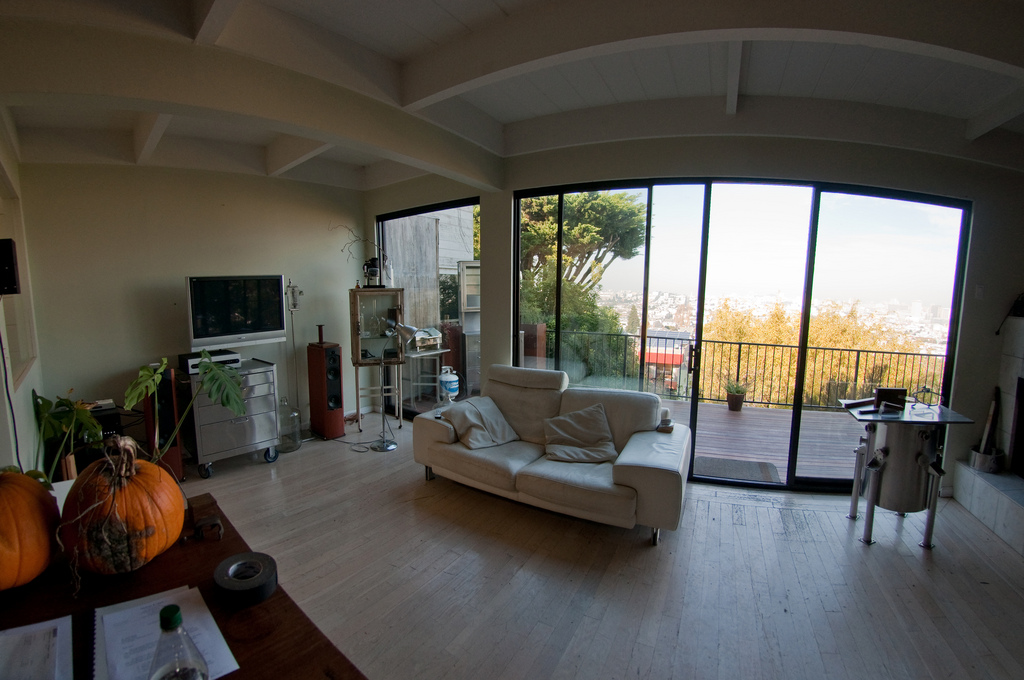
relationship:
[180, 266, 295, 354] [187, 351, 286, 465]
television on cabinet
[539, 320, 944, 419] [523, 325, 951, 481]
railing on deck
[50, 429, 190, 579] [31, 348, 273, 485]
pumpkin with leaves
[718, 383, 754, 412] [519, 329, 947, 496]
plant on patio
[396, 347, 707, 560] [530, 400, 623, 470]
loveseat with pillow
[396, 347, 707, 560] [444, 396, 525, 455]
loveseat with pillow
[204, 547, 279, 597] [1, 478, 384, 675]
tape on counter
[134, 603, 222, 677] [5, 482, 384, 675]
bottle on table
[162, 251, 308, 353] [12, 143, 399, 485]
flatscreentelevision on wall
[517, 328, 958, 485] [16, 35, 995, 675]
balcony behind living room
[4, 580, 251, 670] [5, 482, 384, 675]
paperwork on table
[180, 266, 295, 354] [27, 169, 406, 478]
television on wall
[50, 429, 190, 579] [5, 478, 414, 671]
pumpkin on table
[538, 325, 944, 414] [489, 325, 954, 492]
rail on patio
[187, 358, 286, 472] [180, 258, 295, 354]
cabinet below television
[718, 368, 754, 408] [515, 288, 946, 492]
plant on patio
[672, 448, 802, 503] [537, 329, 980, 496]
floor mat on patio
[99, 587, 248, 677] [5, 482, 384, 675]
papers on table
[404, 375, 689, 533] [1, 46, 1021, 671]
sofa in room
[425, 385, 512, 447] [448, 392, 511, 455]
pillow on sofa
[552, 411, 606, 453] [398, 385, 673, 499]
pillow on sofa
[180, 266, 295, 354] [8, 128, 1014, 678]
television in room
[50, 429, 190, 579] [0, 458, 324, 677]
pumpkin on table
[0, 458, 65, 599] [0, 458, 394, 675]
pumpkin on table